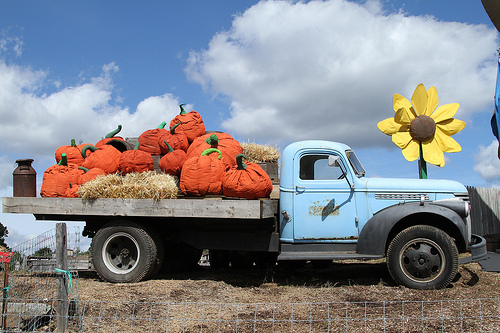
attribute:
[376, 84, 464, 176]
sunflower sculpture — yellow, huge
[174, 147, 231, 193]
pumpkin — fake, orange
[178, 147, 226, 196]
pumpkin — fake, orange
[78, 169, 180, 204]
hay — loose, bunched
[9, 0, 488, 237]
sky — blue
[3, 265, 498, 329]
field — dried-out, grassy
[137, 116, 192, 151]
pumpkin — orange, fake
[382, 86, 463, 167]
sunflower — fake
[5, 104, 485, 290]
truck — light blue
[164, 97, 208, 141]
pumpkin — orange, fake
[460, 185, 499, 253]
fence — unpainted , old, wooden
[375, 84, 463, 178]
fabric sunflower — large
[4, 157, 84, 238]
bucket — rusty, old, milk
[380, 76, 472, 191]
sunflower — yellow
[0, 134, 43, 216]
jug — rusted, metal, milk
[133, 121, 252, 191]
pumpkin — fake, orange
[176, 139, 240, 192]
pumpkin — fabric, orange